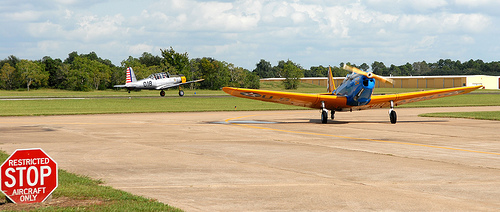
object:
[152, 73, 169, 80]
canopy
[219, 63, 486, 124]
plane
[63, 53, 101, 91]
trees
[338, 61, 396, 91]
propellor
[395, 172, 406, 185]
bench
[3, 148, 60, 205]
board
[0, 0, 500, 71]
clouds/sky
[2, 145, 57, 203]
stop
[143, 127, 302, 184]
sand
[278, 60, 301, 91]
tree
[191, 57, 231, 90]
tree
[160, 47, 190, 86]
tree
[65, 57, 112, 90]
tree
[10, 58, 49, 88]
tree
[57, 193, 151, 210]
grass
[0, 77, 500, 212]
ground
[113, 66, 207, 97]
plane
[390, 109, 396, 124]
wheel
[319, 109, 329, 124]
wheel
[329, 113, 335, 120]
wheel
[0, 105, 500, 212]
runway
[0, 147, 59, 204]
sign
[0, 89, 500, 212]
tarmac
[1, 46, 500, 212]
airport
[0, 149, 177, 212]
earth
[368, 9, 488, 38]
cloud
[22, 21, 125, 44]
cloud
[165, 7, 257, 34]
cloud